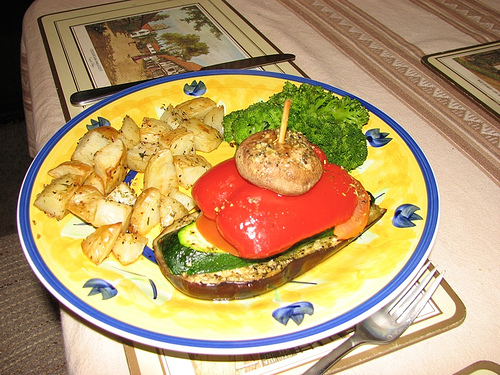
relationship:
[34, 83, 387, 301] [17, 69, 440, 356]
meal on top of plate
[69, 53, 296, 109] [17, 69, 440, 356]
knife next to plate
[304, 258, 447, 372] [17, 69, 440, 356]
fork next to plate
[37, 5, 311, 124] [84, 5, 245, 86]
placemat has picture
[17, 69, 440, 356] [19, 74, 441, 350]
plate has border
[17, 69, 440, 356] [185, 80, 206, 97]
plate has flower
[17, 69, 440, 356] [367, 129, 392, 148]
plate has flower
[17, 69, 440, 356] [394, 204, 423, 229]
plate has flower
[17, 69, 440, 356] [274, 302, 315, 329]
plate has flower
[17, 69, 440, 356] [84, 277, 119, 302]
plate has flower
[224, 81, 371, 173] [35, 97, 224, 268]
broccoli next to potatoes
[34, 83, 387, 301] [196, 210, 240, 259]
meal has tomato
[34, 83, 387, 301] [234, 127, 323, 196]
meal has mushroom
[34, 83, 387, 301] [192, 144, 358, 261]
meal has pepper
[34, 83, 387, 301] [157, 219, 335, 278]
meal has zucchini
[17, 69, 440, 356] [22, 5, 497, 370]
plate on top of tablecloth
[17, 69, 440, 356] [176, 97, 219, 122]
plate has potato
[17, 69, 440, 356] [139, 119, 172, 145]
plate has potato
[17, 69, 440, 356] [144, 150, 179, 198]
plate has potato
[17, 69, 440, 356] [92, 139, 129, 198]
plate has potato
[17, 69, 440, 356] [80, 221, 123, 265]
plate has potatoes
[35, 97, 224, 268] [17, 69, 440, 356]
potatoes are on top of plate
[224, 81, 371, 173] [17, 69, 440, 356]
broccoli on top of plate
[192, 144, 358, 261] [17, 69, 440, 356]
pepper on top of plate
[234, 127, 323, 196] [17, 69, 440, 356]
mushroom on top of plate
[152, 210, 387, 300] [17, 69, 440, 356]
eggplant on top of plate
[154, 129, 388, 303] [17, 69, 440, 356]
sandwich on top of plate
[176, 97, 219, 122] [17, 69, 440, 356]
potato sitting on top of plate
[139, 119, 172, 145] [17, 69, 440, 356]
potato sitting on top of plate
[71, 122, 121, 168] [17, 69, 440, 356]
potato sitting on top of plate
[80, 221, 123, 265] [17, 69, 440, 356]
potatoes sitting on top of plate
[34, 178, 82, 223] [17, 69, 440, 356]
potato sitting on top of plate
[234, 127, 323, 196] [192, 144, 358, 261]
mushroom sitting on top of pepper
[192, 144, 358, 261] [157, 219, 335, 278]
pepper sitting on top of zucchini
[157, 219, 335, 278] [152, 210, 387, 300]
zucchini sitting on top of eggplant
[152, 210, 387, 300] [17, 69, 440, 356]
eggplant lying on top of plate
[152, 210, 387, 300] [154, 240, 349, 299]
eggplant has edge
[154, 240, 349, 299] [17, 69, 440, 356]
edge lying on top of plate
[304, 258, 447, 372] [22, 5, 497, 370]
fork on top of tablecloth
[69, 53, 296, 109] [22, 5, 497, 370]
knife lying on top of tablecloth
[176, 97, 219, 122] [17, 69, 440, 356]
potato on top of plate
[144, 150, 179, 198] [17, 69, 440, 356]
potato on top of plate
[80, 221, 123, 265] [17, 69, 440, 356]
potatoes on top of plate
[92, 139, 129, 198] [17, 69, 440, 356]
potato on top of plate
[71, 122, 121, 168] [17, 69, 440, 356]
potato on top of plate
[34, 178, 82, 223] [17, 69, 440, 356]
potato on top of plate